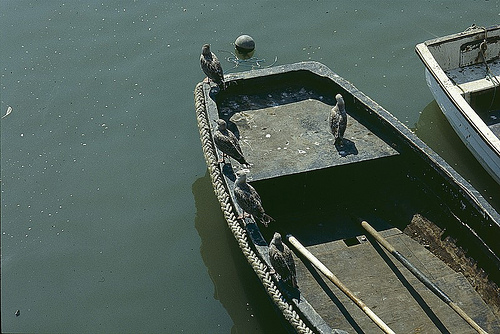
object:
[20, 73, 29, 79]
spot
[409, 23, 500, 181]
boat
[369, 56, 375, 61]
speck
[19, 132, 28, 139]
ripples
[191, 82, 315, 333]
rope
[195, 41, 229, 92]
bird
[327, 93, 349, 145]
bird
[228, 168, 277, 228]
bird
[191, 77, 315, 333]
edge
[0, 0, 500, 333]
water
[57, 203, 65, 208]
spot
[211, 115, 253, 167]
bird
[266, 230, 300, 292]
bird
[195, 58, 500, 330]
boat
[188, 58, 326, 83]
front edge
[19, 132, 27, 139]
spot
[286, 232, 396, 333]
oars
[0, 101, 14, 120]
speck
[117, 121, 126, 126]
spot